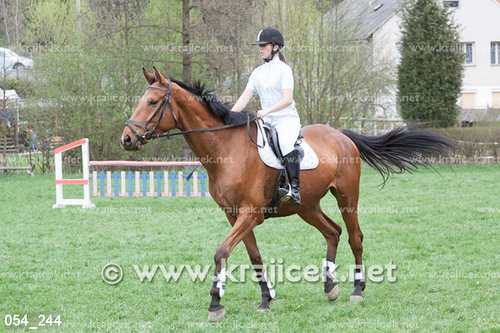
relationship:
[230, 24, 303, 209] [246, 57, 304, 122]
woman wearing shirt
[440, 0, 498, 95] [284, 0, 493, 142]
wall on side of building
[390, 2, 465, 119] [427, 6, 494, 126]
tree in front of white house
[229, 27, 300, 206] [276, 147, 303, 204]
girl wearing boot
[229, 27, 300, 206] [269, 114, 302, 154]
girl wearing pants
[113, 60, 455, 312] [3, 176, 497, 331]
horse on grass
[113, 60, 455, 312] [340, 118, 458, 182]
horse has tail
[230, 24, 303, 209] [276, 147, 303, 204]
woman wearing boot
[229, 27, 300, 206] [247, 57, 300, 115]
girl wearing shirt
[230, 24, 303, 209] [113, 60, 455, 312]
woman riding horse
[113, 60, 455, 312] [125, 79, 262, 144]
horse wearing harness